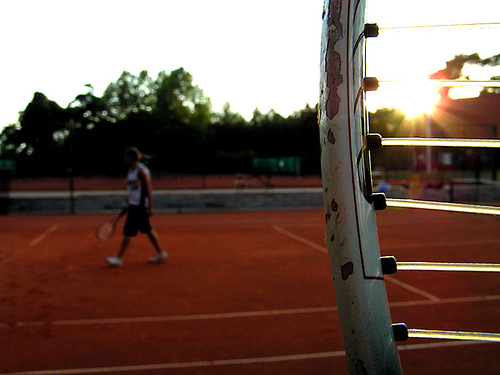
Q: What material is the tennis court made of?
A: RED DIRT.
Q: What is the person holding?
A: Tennis racket.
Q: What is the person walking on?
A: Tennis court.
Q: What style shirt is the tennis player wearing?
A: Muscle shirt.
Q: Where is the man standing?
A: A red tennis court.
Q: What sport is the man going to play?
A: Tennis.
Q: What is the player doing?
A: Walking to the left.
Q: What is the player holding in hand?
A: Tennis racket.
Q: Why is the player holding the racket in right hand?
A: Probably the player is right-handed.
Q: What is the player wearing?
A: Top tank.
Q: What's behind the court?
A: Green trees.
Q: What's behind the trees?
A: Sun rays.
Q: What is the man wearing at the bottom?
A: Black pants.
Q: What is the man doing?
A: Playing tennis.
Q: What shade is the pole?
A: Silver.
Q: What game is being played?
A: Tennis.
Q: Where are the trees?
A: Behind the court.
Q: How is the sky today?
A: Clear.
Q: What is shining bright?
A: The sun.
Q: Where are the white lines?
A: On the court.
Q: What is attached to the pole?
A: Strings.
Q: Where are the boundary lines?
A: On the court.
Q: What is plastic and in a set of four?
A: Posts.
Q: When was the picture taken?
A: In the afternoon.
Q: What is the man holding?
A: A tennis racket.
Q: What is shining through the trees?
A: The Sun.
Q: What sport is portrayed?
A: Tennis.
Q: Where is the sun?
A: On the right.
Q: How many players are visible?
A: 1.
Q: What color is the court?
A: Rust.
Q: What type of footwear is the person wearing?
A: Tennis shoes.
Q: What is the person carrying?
A: Tennis racquet.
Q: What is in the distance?
A: Trees.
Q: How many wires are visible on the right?
A: 6.